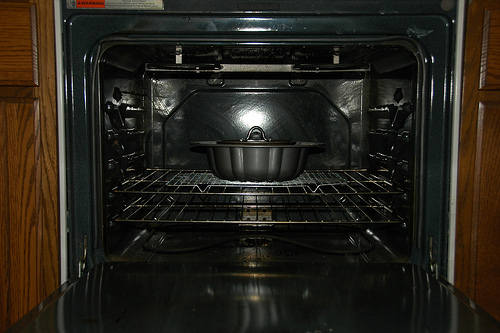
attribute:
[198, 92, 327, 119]
wall — black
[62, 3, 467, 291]
oven — open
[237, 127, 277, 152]
handle — metal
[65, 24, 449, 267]
oven — open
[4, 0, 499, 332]
oven — black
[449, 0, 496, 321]
cabinet — wooden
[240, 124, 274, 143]
handle — curved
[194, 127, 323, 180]
baking pan — silver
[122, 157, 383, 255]
oven rack — metal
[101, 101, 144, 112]
ridge — raised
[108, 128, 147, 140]
ridge — raised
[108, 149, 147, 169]
ridge — raised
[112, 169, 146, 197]
ridge — raised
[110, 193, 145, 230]
ridge — raised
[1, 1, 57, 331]
cabinet — wooden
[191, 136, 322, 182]
cake pan — black